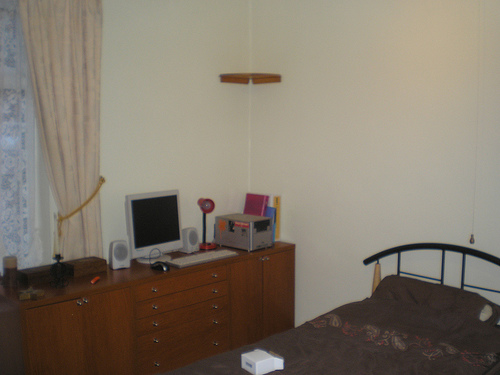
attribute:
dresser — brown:
[5, 214, 279, 369]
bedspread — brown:
[227, 276, 498, 375]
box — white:
[230, 334, 286, 374]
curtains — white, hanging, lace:
[23, 8, 99, 247]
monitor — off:
[130, 184, 187, 250]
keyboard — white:
[179, 244, 234, 286]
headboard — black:
[377, 235, 500, 299]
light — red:
[186, 196, 217, 249]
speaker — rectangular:
[176, 217, 205, 254]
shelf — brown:
[210, 68, 269, 87]